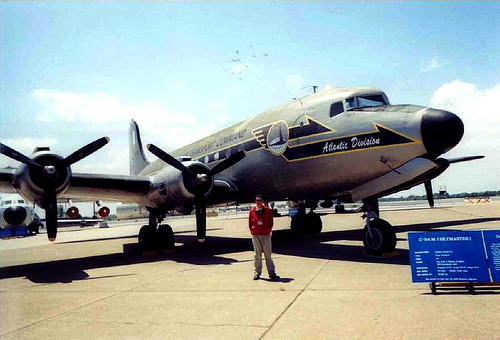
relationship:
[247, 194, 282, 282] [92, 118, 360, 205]
man posing by plane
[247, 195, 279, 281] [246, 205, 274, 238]
man wearing coat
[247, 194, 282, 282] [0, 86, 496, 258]
man in front of airplane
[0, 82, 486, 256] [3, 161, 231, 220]
airplane on wing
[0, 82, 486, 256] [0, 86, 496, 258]
airplane on airplane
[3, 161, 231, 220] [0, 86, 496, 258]
wing on airplane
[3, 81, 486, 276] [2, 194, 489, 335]
airplane on runway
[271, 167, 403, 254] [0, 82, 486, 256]
wheel under airplane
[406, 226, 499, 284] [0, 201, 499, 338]
sign on ground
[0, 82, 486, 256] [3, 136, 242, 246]
airplane has propellers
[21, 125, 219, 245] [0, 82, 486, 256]
propellers are on airplane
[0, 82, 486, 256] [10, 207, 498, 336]
airplane on tarmac